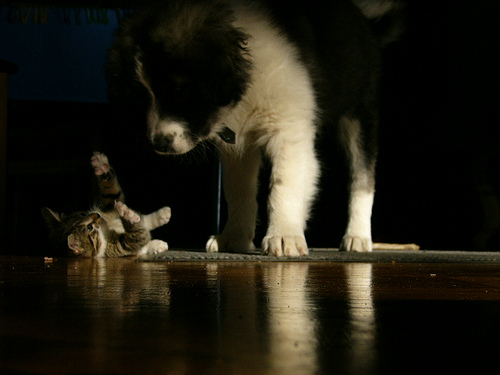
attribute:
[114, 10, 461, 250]
dog — big, black and white, looking, wide, huge, massive, white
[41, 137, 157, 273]
kitten — small, grey, tiny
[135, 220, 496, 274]
rug — gray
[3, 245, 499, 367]
floor — dark, brown, shiny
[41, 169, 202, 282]
kitten — playful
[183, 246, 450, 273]
rug — grey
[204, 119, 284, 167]
collar — black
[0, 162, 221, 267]
kitten — brown and white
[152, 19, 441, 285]
dog — small, fluffy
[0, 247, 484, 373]
floors — brown, wooden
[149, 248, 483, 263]
rug — gray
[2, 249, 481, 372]
floor — wood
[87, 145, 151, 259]
legs — extended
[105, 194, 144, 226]
claw — extended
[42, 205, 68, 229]
ear — perked up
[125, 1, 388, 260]
dog — white, black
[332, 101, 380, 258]
leg — white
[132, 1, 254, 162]
head — black